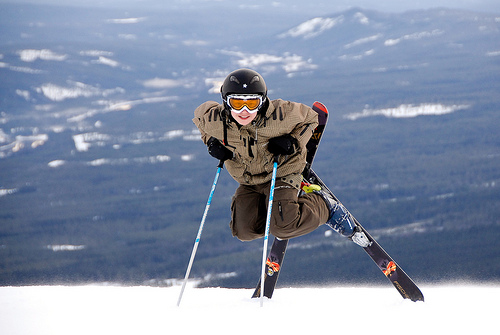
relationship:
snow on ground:
[10, 272, 492, 329] [5, 280, 498, 332]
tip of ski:
[310, 98, 334, 119] [242, 78, 332, 297]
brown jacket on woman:
[190, 96, 320, 186] [194, 67, 329, 239]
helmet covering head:
[217, 72, 275, 129] [222, 92, 263, 126]